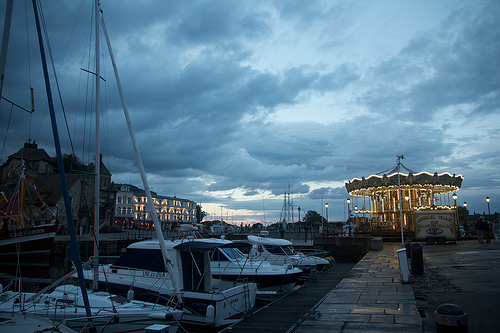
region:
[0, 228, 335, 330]
White boats in parking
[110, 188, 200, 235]
Curved building with many bright lights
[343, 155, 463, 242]
Circular building with bright lights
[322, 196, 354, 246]
Lights on long posts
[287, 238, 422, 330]
Concrete slabs in a long walkway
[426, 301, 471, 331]
Lone bin by the walkway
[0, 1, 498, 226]
Sky filled with clouds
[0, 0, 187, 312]
Tall thin boat masts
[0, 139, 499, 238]
Many buildings along the shore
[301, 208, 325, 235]
Tall tree above distant buildings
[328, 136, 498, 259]
a large round carcsol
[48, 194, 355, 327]
boats in a harbor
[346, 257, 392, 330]
concrete blocks on a walk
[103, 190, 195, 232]
lights on in a building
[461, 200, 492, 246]
people standing in the distance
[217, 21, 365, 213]
a cloudy sky above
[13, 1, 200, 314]
the sail gear for boats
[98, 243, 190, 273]
a blue cover window on boat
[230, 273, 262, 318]
a ladder on boat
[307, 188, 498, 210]
lamp post that are lit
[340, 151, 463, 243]
merry go round on the pier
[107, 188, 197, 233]
large white building on the water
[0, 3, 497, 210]
sky is full of clouds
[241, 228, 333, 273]
white boat docked at the pier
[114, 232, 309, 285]
white boat docked at the pier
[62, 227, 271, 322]
white boat docked at the pier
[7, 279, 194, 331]
white boat docked at the pier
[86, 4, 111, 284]
large white mast of a boat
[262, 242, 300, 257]
window on a white boat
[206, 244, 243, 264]
window on a white boat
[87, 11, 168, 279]
white mast on boat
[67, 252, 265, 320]
boat is color white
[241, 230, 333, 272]
boat is color white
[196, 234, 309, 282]
boat is color white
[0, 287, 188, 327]
boat is color white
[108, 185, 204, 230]
white building with light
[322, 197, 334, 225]
light in a pole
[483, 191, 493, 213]
light in a pole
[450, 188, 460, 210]
light in a pole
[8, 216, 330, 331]
boats in the water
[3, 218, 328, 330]
boats are color white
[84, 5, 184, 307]
the mast of boat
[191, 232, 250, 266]
the cabin has windows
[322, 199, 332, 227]
the light on pole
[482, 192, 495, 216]
the light on pole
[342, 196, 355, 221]
the light on pole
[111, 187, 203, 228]
a building with lights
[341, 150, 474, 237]
the carousel is iluminated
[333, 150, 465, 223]
roof of carousel is green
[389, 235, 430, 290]
trash can on sidewalk